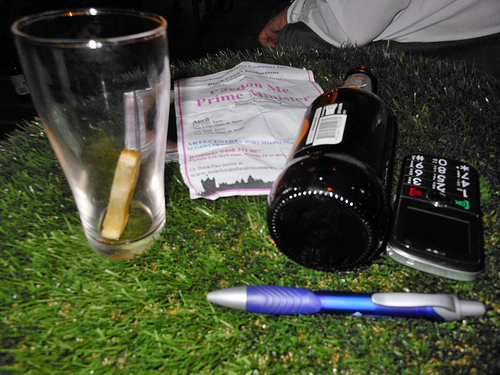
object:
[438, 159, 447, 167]
numbers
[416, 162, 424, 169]
numbers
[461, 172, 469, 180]
numbers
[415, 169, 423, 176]
numbers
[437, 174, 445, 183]
numbers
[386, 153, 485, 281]
cell phone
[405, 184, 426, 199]
red button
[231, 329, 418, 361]
grass patch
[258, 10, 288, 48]
hand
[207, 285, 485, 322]
blue pen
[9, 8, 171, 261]
glass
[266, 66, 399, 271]
bottle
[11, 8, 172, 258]
cup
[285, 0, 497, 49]
shirt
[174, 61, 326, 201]
paper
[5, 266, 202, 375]
grass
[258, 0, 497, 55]
person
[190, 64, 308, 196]
prints